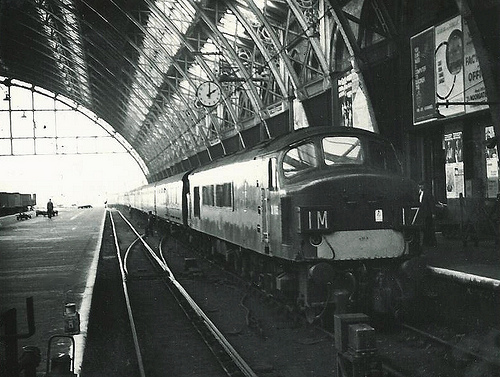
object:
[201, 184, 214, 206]
window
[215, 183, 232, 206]
window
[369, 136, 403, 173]
window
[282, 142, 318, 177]
window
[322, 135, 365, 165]
window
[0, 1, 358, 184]
roof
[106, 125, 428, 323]
train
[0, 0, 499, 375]
station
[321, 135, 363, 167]
reflection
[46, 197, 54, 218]
person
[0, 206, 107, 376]
concrete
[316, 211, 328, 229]
letters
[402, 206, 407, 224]
numbers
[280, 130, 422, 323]
front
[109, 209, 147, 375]
train tracks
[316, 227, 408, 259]
bumper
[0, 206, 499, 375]
ground